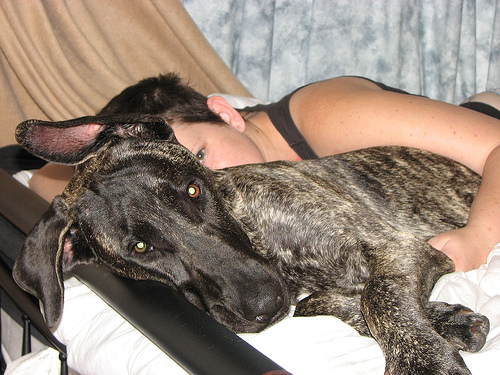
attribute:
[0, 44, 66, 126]
drape — brown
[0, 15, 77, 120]
drape — brown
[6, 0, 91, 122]
drape — brown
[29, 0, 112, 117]
drape — brown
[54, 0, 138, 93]
drape — brown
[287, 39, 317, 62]
drapes — marbled